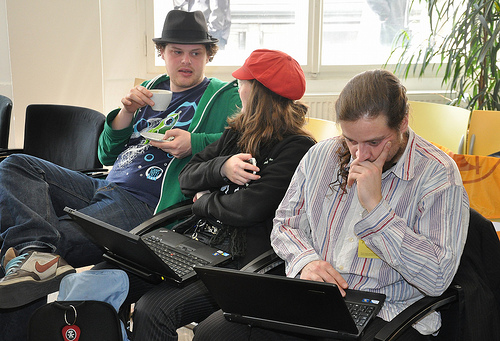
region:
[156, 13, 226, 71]
the hat the guy is wearing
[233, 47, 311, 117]
the hat the girl is wearing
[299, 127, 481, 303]
the guy in the white striped shirt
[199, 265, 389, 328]
the keyboard the guy in white is using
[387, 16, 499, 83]
the tree that is behind them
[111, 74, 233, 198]
the guy's green sweatshirt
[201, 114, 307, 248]
the girl's black jacket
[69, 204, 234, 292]
the girl's laptop she is using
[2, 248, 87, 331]
the guy in green's nike sneakers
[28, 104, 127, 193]
the empty chair next to the guy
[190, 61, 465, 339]
person on a couch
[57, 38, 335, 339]
person on a couch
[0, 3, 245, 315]
person on a couch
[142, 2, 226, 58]
medium sized black hat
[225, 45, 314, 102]
red hat with bill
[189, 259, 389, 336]
black plastic laptop computer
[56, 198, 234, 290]
black plastic laptop computer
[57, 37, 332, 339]
person wearing black shirt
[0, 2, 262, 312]
person wearing green sweater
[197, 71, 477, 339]
person with brown hair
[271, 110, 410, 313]
man is working on his laptop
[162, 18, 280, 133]
the two people are talking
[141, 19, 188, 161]
he is holding a cup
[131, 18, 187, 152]
he is holding a suacer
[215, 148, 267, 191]
she's holding a phone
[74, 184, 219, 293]
the la[top is on her lap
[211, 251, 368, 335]
the laptop is on his lap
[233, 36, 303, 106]
the hat is red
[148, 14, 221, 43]
the hat is black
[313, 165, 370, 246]
the shirt is stripped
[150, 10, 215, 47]
a man's black hat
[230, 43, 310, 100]
a red cap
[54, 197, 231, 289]
a black laptop computer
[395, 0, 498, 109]
part of a green tree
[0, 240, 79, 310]
a man's tennis shoe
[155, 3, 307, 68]
part of a window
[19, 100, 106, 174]
part of a black seat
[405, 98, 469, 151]
part of a yellow seat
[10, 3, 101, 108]
part of a white wall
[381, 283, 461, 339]
the arm of a chair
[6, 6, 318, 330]
A man and a woman talking to each other.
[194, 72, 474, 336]
A man sitting down looking at his laptop computer.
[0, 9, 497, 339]
Three people sitting beside each other.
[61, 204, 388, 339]
Two black laptop computers.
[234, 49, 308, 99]
An orange-red hat.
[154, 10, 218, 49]
A black hat.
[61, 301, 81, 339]
A red keychain.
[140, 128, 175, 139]
A small white saucer.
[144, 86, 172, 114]
A small white teacup.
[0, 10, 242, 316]
A guy sitting down holding a teacup up.